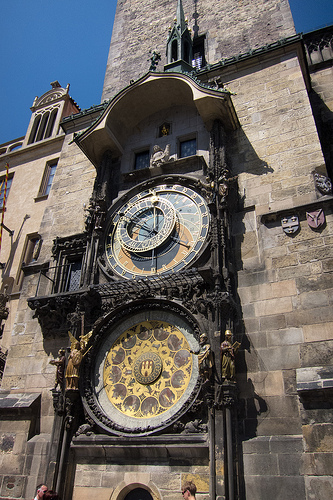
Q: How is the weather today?
A: It is cloudless.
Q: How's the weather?
A: It is cloudless.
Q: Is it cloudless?
A: Yes, it is cloudless.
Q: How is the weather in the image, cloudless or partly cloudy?
A: It is cloudless.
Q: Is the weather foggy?
A: No, it is cloudless.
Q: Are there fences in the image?
A: No, there are no fences.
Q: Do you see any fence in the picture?
A: No, there are no fences.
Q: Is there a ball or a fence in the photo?
A: No, there are no fences or balls.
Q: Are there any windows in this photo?
A: Yes, there is a window.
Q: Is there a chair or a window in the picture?
A: Yes, there is a window.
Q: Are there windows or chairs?
A: Yes, there is a window.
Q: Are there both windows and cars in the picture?
A: No, there is a window but no cars.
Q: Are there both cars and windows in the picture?
A: No, there is a window but no cars.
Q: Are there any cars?
A: No, there are no cars.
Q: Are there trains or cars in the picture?
A: No, there are no cars or trains.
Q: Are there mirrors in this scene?
A: No, there are no mirrors.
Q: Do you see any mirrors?
A: No, there are no mirrors.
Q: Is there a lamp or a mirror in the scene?
A: No, there are no mirrors or lamps.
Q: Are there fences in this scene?
A: No, there are no fences.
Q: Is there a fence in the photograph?
A: No, there are no fences.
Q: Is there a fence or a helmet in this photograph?
A: No, there are no fences or helmets.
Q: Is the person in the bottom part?
A: Yes, the person is in the bottom of the image.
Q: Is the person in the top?
A: No, the person is in the bottom of the image.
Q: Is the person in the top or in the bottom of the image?
A: The person is in the bottom of the image.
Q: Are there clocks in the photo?
A: Yes, there is a clock.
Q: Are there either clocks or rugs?
A: Yes, there is a clock.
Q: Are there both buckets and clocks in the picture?
A: No, there is a clock but no buckets.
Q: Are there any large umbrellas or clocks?
A: Yes, there is a large clock.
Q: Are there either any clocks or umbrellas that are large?
A: Yes, the clock is large.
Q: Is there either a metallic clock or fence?
A: Yes, there is a metal clock.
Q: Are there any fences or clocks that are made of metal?
A: Yes, the clock is made of metal.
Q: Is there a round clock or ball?
A: Yes, there is a round clock.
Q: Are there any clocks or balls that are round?
A: Yes, the clock is round.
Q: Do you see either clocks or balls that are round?
A: Yes, the clock is round.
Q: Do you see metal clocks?
A: Yes, there is a metal clock.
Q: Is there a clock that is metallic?
A: Yes, there is a clock that is metallic.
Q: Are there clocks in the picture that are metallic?
A: Yes, there is a clock that is metallic.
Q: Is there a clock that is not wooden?
A: Yes, there is a metallic clock.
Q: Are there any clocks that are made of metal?
A: Yes, there is a clock that is made of metal.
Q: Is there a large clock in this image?
A: Yes, there is a large clock.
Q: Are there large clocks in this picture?
A: Yes, there is a large clock.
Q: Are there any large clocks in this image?
A: Yes, there is a large clock.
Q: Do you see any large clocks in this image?
A: Yes, there is a large clock.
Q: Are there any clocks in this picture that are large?
A: Yes, there is a clock that is large.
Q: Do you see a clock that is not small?
A: Yes, there is a large clock.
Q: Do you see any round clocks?
A: Yes, there is a round clock.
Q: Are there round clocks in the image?
A: Yes, there is a round clock.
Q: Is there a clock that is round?
A: Yes, there is a clock that is round.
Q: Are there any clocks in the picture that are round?
A: Yes, there is a clock that is round.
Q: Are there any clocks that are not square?
A: Yes, there is a round clock.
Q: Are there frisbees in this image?
A: No, there are no frisbees.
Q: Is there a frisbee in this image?
A: No, there are no frisbees.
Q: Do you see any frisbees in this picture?
A: No, there are no frisbees.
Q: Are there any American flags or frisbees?
A: No, there are no frisbees or American flags.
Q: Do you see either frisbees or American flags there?
A: No, there are no frisbees or American flags.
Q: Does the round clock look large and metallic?
A: Yes, the clock is large and metallic.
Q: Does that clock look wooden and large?
A: No, the clock is large but metallic.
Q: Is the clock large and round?
A: Yes, the clock is large and round.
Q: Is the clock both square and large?
A: No, the clock is large but round.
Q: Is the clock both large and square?
A: No, the clock is large but round.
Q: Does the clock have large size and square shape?
A: No, the clock is large but round.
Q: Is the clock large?
A: Yes, the clock is large.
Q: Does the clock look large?
A: Yes, the clock is large.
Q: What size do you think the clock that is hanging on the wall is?
A: The clock is large.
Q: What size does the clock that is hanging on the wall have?
A: The clock has large size.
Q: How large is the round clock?
A: The clock is large.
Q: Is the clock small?
A: No, the clock is large.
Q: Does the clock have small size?
A: No, the clock is large.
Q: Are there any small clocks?
A: No, there is a clock but it is large.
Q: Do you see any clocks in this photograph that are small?
A: No, there is a clock but it is large.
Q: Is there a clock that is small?
A: No, there is a clock but it is large.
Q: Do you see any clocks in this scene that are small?
A: No, there is a clock but it is large.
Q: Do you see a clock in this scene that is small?
A: No, there is a clock but it is large.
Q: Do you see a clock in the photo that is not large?
A: No, there is a clock but it is large.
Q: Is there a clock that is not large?
A: No, there is a clock but it is large.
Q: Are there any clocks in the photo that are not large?
A: No, there is a clock but it is large.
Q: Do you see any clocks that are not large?
A: No, there is a clock but it is large.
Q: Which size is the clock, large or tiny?
A: The clock is large.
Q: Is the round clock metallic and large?
A: Yes, the clock is metallic and large.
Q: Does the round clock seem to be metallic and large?
A: Yes, the clock is metallic and large.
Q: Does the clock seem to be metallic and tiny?
A: No, the clock is metallic but large.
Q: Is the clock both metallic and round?
A: Yes, the clock is metallic and round.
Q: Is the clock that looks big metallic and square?
A: No, the clock is metallic but round.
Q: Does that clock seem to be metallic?
A: Yes, the clock is metallic.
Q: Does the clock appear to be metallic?
A: Yes, the clock is metallic.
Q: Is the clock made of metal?
A: Yes, the clock is made of metal.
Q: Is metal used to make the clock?
A: Yes, the clock is made of metal.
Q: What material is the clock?
A: The clock is made of metal.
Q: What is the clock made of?
A: The clock is made of metal.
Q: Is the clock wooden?
A: No, the clock is metallic.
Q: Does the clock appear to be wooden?
A: No, the clock is metallic.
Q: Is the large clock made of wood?
A: No, the clock is made of metal.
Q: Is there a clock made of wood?
A: No, there is a clock but it is made of metal.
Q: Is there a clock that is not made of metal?
A: No, there is a clock but it is made of metal.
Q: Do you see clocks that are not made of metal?
A: No, there is a clock but it is made of metal.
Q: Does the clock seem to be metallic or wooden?
A: The clock is metallic.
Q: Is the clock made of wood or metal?
A: The clock is made of metal.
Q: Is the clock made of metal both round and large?
A: Yes, the clock is round and large.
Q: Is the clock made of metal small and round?
A: No, the clock is round but large.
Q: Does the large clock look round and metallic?
A: Yes, the clock is round and metallic.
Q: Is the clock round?
A: Yes, the clock is round.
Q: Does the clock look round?
A: Yes, the clock is round.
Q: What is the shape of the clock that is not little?
A: The clock is round.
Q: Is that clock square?
A: No, the clock is round.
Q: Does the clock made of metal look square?
A: No, the clock is round.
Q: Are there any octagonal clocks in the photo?
A: No, there is a clock but it is round.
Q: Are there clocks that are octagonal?
A: No, there is a clock but it is round.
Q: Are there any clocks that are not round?
A: No, there is a clock but it is round.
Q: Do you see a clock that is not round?
A: No, there is a clock but it is round.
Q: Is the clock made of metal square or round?
A: The clock is round.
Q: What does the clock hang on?
A: The clock hangs on the wall.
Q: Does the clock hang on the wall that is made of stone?
A: Yes, the clock hangs on the wall.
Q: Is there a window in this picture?
A: Yes, there is a window.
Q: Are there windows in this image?
A: Yes, there is a window.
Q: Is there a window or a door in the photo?
A: Yes, there is a window.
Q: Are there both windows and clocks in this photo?
A: Yes, there are both a window and a clock.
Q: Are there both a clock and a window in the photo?
A: Yes, there are both a window and a clock.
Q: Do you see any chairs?
A: No, there are no chairs.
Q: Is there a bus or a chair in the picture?
A: No, there are no chairs or buses.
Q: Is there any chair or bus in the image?
A: No, there are no chairs or buses.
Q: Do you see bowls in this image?
A: No, there are no bowls.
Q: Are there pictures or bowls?
A: No, there are no bowls or pictures.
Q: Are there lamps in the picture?
A: No, there are no lamps.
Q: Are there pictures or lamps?
A: No, there are no lamps or pictures.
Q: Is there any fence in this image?
A: No, there are no fences.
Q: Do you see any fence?
A: No, there are no fences.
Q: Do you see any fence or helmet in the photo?
A: No, there are no fences or helmets.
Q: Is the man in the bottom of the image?
A: Yes, the man is in the bottom of the image.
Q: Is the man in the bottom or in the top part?
A: The man is in the bottom of the image.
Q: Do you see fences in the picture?
A: No, there are no fences.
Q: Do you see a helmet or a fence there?
A: No, there are no fences or helmets.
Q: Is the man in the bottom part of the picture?
A: Yes, the man is in the bottom of the image.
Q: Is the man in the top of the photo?
A: No, the man is in the bottom of the image.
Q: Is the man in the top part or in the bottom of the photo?
A: The man is in the bottom of the image.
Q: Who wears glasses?
A: The man wears glasses.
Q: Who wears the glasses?
A: The man wears glasses.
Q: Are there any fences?
A: No, there are no fences.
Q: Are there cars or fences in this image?
A: No, there are no fences or cars.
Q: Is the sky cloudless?
A: Yes, the sky is cloudless.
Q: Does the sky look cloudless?
A: Yes, the sky is cloudless.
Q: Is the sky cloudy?
A: No, the sky is cloudless.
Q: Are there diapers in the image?
A: No, there are no diapers.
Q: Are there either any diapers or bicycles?
A: No, there are no diapers or bicycles.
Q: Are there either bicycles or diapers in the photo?
A: No, there are no diapers or bicycles.